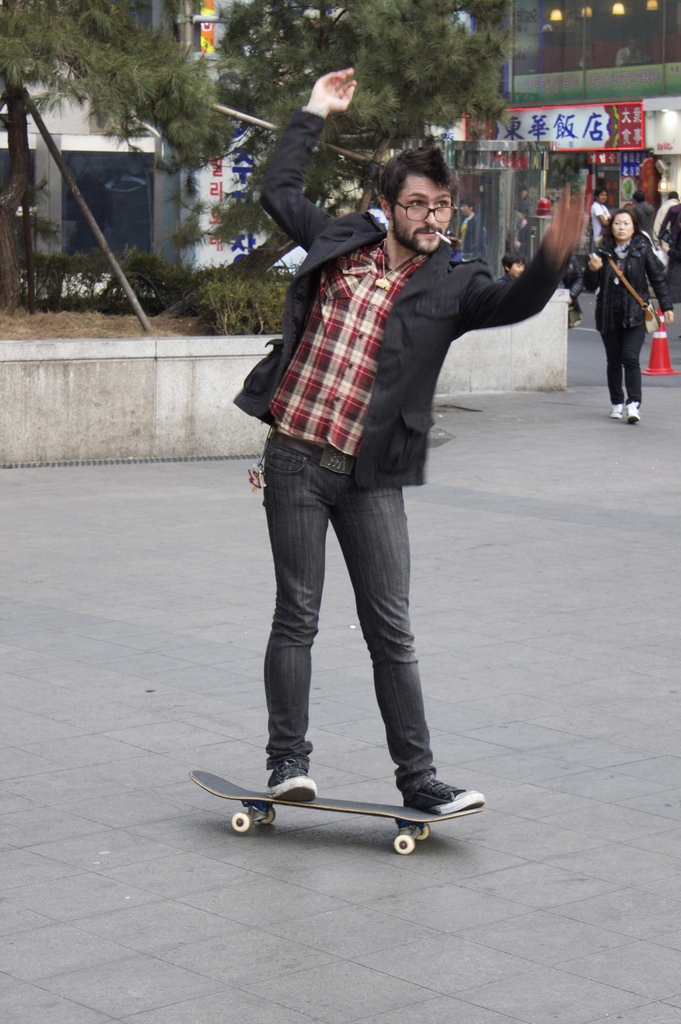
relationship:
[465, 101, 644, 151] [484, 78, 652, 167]
letter on sign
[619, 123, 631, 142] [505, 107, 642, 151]
letter on sign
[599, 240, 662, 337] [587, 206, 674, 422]
brown purse by woman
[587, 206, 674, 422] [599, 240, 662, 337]
woman has brown purse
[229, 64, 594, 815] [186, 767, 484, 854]
man riding skateboard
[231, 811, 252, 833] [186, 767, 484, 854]
wheel mounted on skateboard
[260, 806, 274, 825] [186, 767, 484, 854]
wheel mounted on skateboard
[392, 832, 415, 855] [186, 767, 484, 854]
wheel mounted on skateboard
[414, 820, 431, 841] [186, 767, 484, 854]
wheel mounted on skateboard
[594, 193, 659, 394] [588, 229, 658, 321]
woman in jacket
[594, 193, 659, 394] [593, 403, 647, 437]
woman in shoes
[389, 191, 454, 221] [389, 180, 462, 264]
eyeglasses on face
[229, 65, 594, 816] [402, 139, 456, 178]
man has hair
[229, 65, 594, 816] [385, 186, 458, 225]
man has glasses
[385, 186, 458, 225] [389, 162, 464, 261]
glasses on face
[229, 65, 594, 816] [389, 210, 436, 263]
man has hair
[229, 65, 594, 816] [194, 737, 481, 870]
man standing skateboard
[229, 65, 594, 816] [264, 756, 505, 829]
man wearing shoes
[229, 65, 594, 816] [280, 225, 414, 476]
man wearing shirt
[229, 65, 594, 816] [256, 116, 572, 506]
man wearing jacket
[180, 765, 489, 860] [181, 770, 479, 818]
skateboard with top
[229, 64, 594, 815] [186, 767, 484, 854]
man on skateboard